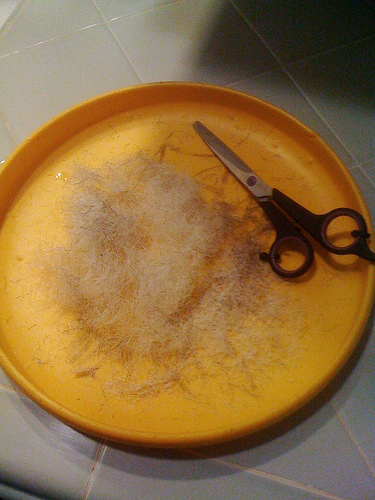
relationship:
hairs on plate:
[44, 130, 293, 387] [107, 90, 369, 270]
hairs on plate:
[68, 151, 267, 382] [1, 80, 367, 451]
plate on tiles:
[1, 80, 367, 451] [1, 0, 373, 494]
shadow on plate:
[164, 4, 373, 175] [1, 80, 367, 451]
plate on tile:
[1, 80, 367, 451] [1, 1, 368, 498]